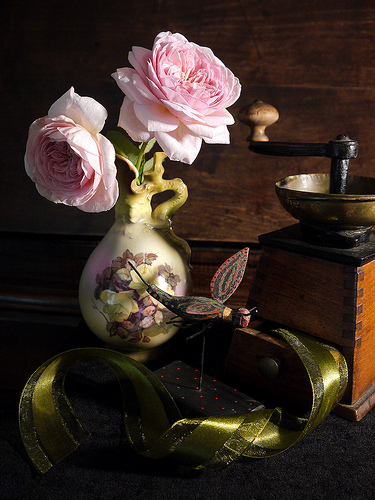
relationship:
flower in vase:
[22, 83, 120, 214] [77, 139, 196, 369]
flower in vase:
[112, 30, 242, 167] [77, 139, 196, 369]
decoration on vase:
[91, 248, 182, 342] [78, 152, 201, 352]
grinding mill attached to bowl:
[237, 99, 359, 196] [273, 172, 365, 232]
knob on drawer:
[255, 355, 284, 380] [219, 329, 312, 412]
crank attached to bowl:
[252, 101, 353, 181] [278, 149, 373, 222]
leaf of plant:
[106, 131, 154, 185] [17, 25, 240, 214]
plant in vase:
[17, 25, 240, 214] [78, 152, 201, 352]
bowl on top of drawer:
[272, 172, 372, 223] [224, 317, 348, 410]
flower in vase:
[22, 83, 120, 214] [70, 217, 196, 339]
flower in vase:
[112, 30, 242, 167] [70, 217, 196, 339]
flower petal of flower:
[47, 86, 108, 137] [5, 93, 123, 218]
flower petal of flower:
[95, 133, 117, 190] [5, 93, 123, 218]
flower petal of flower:
[77, 177, 120, 212] [5, 93, 123, 218]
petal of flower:
[55, 124, 97, 156] [5, 93, 123, 218]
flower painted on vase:
[98, 290, 138, 323] [77, 152, 192, 359]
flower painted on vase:
[128, 265, 158, 292] [77, 152, 192, 359]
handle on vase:
[151, 174, 186, 223] [77, 152, 192, 359]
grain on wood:
[205, 167, 261, 229] [2, 74, 374, 243]